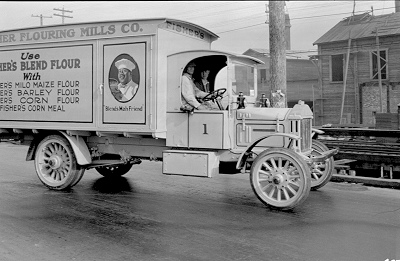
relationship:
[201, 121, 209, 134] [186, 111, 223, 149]
1 on door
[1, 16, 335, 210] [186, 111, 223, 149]
truck has door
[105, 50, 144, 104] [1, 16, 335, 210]
baker on truck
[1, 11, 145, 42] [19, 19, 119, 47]
company calls flowering mills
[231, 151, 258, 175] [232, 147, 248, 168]
guard has edge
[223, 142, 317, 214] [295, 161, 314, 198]
wheel has edge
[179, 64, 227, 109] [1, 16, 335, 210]
driver in truck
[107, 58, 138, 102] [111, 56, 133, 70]
baker has baker's hat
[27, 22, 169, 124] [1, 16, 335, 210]
cargo on truck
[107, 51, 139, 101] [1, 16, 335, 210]
picture on truck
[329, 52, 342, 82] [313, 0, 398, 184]
window on building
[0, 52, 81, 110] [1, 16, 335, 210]
writing on truck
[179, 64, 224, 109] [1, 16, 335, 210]
driver driving truck